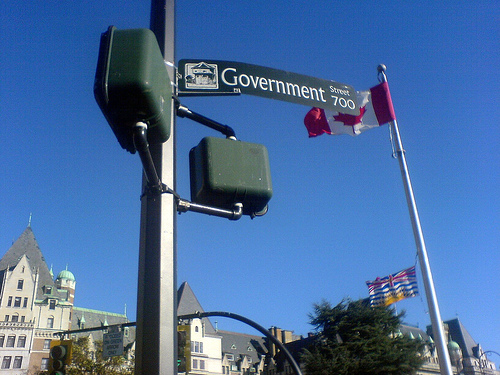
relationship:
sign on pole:
[183, 57, 350, 108] [130, 221, 186, 302]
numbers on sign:
[331, 91, 357, 109] [183, 57, 350, 108]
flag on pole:
[370, 263, 429, 303] [401, 150, 422, 226]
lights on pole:
[43, 341, 72, 372] [100, 324, 127, 332]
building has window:
[4, 245, 54, 373] [14, 277, 28, 289]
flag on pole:
[370, 263, 429, 303] [130, 221, 186, 302]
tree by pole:
[337, 329, 356, 344] [130, 221, 186, 302]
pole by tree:
[130, 221, 186, 302] [337, 329, 356, 344]